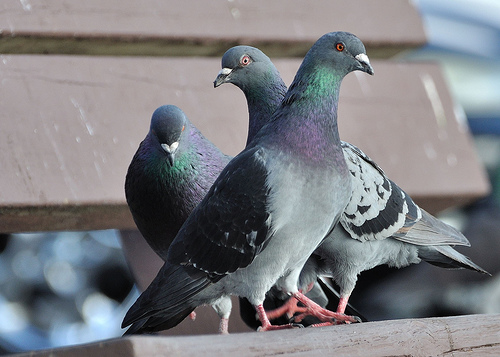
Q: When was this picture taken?
A: Daytime.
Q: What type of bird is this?
A: Pigeon.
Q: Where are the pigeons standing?
A: Bench.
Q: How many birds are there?
A: 3.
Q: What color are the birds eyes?
A: Orange.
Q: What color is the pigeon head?
A: Grey.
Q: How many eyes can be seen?
A: 2.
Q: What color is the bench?
A: Brown.